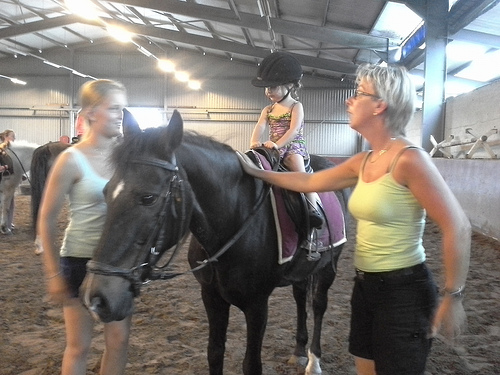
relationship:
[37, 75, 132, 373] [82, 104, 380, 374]
girl near horse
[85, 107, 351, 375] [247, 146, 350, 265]
black horse with blanket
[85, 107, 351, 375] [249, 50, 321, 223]
black horse with child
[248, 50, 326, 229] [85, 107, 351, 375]
girl riding black horse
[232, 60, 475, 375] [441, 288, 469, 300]
lady with watch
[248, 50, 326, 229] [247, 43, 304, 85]
girl with helmet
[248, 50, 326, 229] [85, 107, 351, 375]
girl on black horse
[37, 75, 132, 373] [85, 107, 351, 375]
girl standing next to black horse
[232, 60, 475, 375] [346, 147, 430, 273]
lady wearing top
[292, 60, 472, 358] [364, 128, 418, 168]
lady wearing necklace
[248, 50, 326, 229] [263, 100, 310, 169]
girl wearing dress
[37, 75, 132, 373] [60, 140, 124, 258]
girl wearing tank top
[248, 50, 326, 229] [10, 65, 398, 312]
girl riding a horse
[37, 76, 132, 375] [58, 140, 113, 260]
girl in a tank top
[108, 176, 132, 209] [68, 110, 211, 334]
white diamond on head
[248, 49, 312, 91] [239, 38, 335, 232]
helmet on child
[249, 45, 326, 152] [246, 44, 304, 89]
girl wears helmet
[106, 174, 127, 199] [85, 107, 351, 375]
diamond on black horse